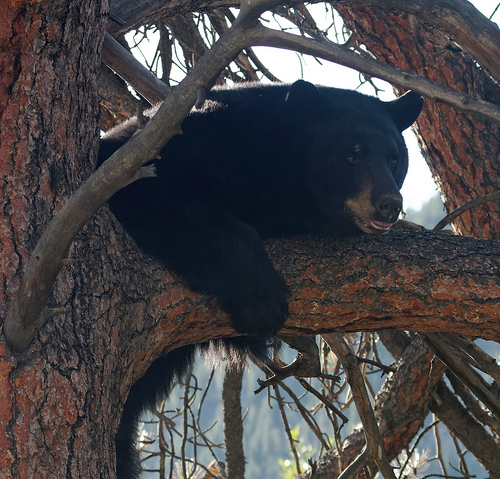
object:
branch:
[300, 336, 449, 479]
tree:
[0, 0, 498, 475]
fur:
[216, 128, 245, 146]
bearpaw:
[216, 277, 296, 342]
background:
[0, 0, 499, 478]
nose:
[371, 190, 403, 222]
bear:
[92, 79, 423, 479]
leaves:
[278, 423, 307, 477]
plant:
[278, 418, 313, 477]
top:
[317, 86, 397, 128]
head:
[261, 72, 429, 241]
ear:
[280, 74, 323, 121]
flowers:
[385, 443, 428, 477]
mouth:
[359, 211, 401, 241]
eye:
[343, 147, 363, 169]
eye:
[382, 150, 407, 172]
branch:
[113, 217, 500, 376]